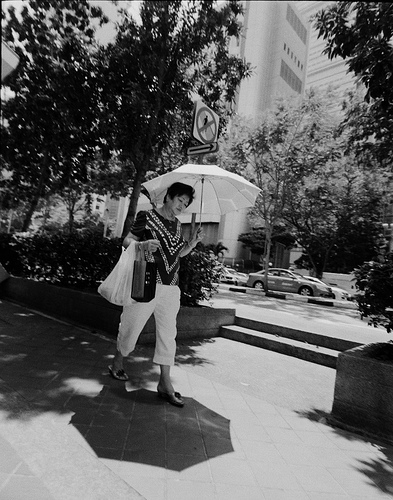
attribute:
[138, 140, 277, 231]
umbrella — large, white, open, shielding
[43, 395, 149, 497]
ground — asphalt, white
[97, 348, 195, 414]
shoes — thongs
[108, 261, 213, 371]
cargo pants — white, cropped, capris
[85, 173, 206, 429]
woman — carrying, walking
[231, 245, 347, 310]
car — parked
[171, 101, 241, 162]
circle — white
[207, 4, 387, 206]
building — white, large, tall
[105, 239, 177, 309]
bag — plastic, hanging, white, black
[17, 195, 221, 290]
hedge — small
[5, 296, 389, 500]
street — concrete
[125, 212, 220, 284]
top — graphic, designed, black, white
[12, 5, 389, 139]
weather — incelement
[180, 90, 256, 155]
sign — overhead, white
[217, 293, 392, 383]
steps — concrete